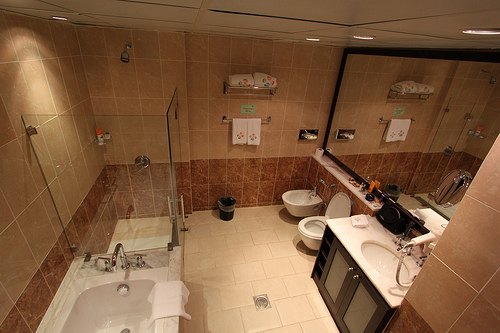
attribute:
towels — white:
[230, 112, 266, 150]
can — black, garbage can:
[216, 193, 241, 224]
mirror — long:
[321, 46, 496, 240]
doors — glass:
[163, 87, 193, 246]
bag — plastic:
[213, 195, 243, 210]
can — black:
[216, 199, 236, 224]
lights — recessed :
[297, 30, 323, 46]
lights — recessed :
[342, 29, 378, 46]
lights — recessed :
[458, 23, 498, 42]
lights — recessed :
[47, 9, 69, 20]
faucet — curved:
[106, 241, 136, 275]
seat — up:
[297, 188, 352, 240]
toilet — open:
[297, 189, 352, 249]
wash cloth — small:
[350, 212, 368, 229]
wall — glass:
[25, 77, 191, 251]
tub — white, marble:
[45, 245, 182, 332]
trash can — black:
[214, 195, 236, 222]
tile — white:
[262, 255, 301, 280]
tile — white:
[230, 260, 266, 283]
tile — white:
[251, 227, 281, 248]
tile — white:
[197, 232, 232, 254]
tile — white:
[267, 290, 320, 327]